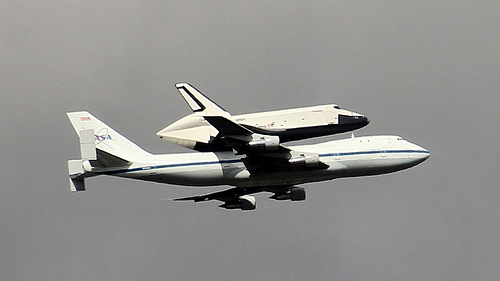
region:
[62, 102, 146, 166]
the tail of a plane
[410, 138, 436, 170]
the nose of a plane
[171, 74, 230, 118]
the tail of a space shuttle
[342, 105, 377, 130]
the nose of a space shuttle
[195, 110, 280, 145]
the wing of the space shuttle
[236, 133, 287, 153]
the engine of the plane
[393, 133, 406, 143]
the windshield of the plane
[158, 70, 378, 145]
a white and black space shuttle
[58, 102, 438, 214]
a white plane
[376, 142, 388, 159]
a door on the plane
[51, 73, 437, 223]
shuttle riding piggyback on plane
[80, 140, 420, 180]
dark line dividing plane in half horizontally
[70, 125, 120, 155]
aeronautics logo partially covered on tail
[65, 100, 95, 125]
reverse flag on tail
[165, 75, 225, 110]
blacks borders on tail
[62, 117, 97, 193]
grey panels at different heights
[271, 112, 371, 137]
black underside of shuttle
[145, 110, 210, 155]
pointed formation on back of shuttle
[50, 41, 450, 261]
solid grey background of sky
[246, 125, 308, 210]
plane engines in light and shade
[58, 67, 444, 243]
A NASA airplane in the sky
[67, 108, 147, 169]
NASA logo on tail wing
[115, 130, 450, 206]
blue long stripe on on airplane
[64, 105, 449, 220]
white and blue colored airplane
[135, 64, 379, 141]
white and black space shuttle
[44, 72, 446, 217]
Airplane carrying NASA space shuttle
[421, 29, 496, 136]
gray sky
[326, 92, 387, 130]
black tip on space shuttle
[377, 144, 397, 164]
side door of airplane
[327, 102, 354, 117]
dark window on space shuttle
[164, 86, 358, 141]
a small white plane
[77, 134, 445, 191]
a large white plane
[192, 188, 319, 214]
the landing gear of a large plane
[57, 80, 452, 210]
a small white plane being carried by a large plane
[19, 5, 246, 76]
an expanse of hazy sky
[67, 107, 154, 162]
the tail fin of a large plane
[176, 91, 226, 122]
the tail fin of a small plane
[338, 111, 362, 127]
the black nose of a small plane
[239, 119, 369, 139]
the black undercarriage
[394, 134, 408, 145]
the windshield of a large plane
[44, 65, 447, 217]
Two airplanes in the sky.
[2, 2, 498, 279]
Black and white filter.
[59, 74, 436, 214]
The airplanes are white.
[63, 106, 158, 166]
The tail is tall.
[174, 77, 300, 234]
Wings on the side of the plane.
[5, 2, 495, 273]
The sky is clear.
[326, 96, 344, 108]
Windows on the front of plane.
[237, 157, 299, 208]
No wheels visible.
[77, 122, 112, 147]
The tail says USA.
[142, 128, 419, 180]
No side windows on the plane.